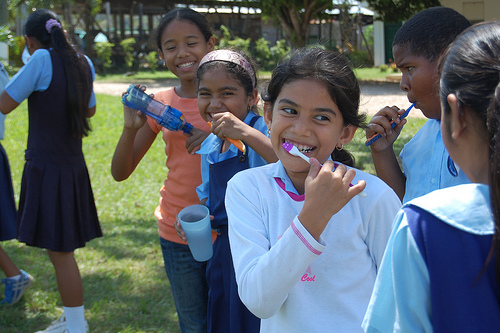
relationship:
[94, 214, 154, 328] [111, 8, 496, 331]
grass below children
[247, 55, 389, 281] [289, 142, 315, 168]
kid brushing teeth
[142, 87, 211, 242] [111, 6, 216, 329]
shirt on child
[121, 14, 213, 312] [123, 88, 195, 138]
girl holding bottle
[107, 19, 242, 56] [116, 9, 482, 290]
bushes behind kids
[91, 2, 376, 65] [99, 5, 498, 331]
fence behind kids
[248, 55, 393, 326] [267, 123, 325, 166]
girl brushing teeth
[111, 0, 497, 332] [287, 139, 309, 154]
children brushing teeth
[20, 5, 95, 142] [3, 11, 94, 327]
hair of girl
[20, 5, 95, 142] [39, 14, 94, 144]
hair in a ponytail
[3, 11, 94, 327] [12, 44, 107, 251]
girl wearing jumper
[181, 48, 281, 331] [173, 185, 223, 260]
kid holding cup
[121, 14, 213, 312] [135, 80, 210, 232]
girl in shirt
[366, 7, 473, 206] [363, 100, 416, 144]
boy holding toothbrush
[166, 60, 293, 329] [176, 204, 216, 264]
girl holding cup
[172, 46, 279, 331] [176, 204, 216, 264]
child holding cup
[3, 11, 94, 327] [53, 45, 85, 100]
girl with hair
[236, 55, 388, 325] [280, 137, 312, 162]
kid using toothbrush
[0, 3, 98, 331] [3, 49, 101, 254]
kid wearing school uniform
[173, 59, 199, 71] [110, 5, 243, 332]
smile of girl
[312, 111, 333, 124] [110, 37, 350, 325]
eye of kid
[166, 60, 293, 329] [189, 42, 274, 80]
girl wearing headband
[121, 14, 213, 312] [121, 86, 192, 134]
girl holding bottle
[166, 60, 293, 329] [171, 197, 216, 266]
girl holding glass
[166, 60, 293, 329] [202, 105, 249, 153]
girl holding toothbrush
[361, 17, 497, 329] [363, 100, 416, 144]
girl holding toothbrush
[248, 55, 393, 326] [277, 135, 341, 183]
girl holding toothbrush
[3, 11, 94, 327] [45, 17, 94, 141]
girl with ponytail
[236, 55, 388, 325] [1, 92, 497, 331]
kid standing on grass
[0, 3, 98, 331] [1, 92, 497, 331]
kid standing on grass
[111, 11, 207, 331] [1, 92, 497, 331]
kids standing on grass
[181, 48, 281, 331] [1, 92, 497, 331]
kid standing on grass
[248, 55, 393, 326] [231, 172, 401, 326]
girl wearing sweater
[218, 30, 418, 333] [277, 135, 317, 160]
child brushing teeth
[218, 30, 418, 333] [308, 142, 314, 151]
child brushing teeth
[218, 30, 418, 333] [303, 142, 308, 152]
child brushing teeth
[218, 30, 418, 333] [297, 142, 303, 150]
child brushing teeth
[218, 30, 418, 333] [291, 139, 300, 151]
child brushing teeth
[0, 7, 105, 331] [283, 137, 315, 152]
child brushing teeth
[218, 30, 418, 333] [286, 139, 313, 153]
child brushing teeth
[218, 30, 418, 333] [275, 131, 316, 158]
child brushing teeth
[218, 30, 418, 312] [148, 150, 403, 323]
child wearing sweater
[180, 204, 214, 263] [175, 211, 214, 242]
cup in hand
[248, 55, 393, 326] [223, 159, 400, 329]
girl wearing shirt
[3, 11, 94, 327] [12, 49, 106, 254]
girl wearing dress